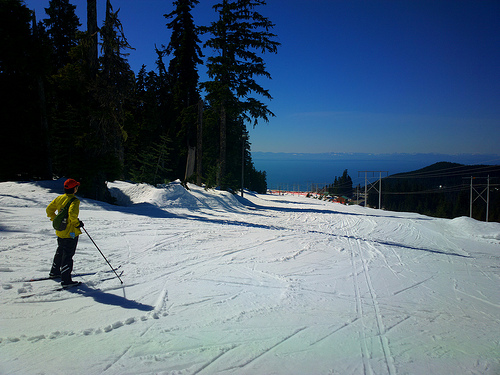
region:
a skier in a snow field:
[31, 170, 362, 332]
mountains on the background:
[256, 142, 496, 206]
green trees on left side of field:
[0, 4, 269, 188]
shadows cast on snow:
[176, 185, 446, 274]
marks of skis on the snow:
[296, 208, 416, 374]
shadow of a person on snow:
[52, 280, 167, 327]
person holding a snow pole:
[40, 176, 136, 296]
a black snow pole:
[76, 220, 131, 294]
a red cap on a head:
[46, 171, 88, 206]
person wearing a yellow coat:
[38, 173, 93, 290]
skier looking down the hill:
[22, 177, 124, 299]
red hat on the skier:
[62, 178, 81, 191]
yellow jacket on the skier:
[43, 193, 82, 239]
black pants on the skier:
[48, 235, 80, 285]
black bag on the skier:
[51, 195, 78, 231]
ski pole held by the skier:
[71, 220, 134, 281]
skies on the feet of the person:
[11, 260, 127, 301]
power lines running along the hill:
[268, 163, 498, 218]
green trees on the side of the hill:
[0, 0, 270, 201]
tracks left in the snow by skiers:
[1, 188, 498, 373]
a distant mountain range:
[277, 143, 481, 167]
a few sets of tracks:
[296, 195, 451, 270]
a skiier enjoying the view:
[17, 174, 136, 299]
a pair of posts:
[354, 165, 391, 210]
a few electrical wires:
[373, 163, 482, 204]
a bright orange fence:
[269, 186, 322, 196]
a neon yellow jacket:
[43, 191, 84, 243]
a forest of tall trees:
[8, 0, 273, 191]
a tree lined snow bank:
[115, 135, 232, 209]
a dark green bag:
[48, 193, 74, 234]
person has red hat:
[47, 166, 90, 196]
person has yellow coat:
[49, 196, 83, 233]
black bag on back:
[51, 201, 86, 238]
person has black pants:
[44, 218, 82, 308]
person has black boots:
[43, 266, 77, 293]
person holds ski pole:
[69, 209, 126, 301]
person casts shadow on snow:
[51, 273, 156, 321]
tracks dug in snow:
[0, 291, 173, 346]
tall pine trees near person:
[0, 9, 282, 195]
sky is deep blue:
[301, 9, 495, 164]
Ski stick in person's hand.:
[75, 215, 126, 278]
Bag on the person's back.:
[53, 200, 73, 232]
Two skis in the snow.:
[13, 261, 137, 292]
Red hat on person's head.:
[60, 178, 81, 193]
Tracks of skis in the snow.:
[323, 214, 393, 374]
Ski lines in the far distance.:
[353, 156, 495, 219]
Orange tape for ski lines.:
[270, 180, 327, 199]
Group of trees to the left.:
[141, 84, 239, 189]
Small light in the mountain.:
[431, 178, 447, 193]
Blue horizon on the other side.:
[312, 96, 424, 168]